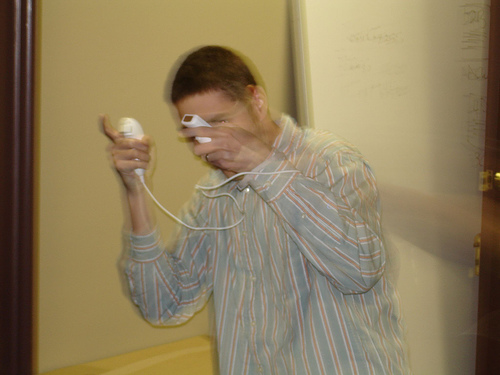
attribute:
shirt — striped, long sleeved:
[121, 112, 410, 374]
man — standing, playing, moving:
[102, 45, 412, 374]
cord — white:
[139, 169, 300, 230]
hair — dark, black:
[171, 45, 259, 133]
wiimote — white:
[181, 113, 215, 144]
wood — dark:
[0, 0, 41, 374]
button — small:
[243, 186, 251, 194]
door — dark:
[474, 0, 499, 374]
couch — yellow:
[41, 333, 217, 374]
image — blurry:
[0, 0, 499, 372]